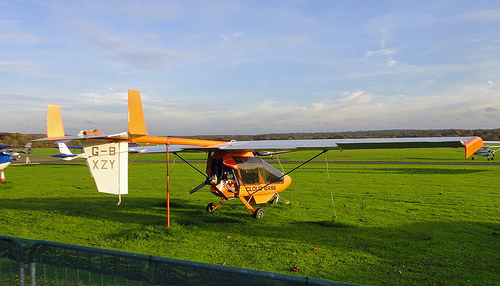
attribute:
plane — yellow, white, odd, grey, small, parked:
[19, 81, 485, 222]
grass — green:
[3, 145, 498, 283]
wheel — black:
[253, 209, 268, 224]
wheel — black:
[205, 202, 216, 215]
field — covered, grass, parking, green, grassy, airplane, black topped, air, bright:
[2, 120, 495, 283]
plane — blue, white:
[0, 147, 19, 183]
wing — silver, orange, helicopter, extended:
[129, 82, 490, 162]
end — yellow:
[125, 86, 145, 139]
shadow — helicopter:
[3, 184, 414, 257]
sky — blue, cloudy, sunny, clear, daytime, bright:
[2, 1, 499, 141]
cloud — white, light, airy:
[72, 75, 498, 128]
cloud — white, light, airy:
[340, 31, 500, 78]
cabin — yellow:
[198, 151, 294, 211]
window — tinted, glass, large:
[238, 153, 283, 187]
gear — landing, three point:
[200, 191, 293, 222]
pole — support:
[164, 144, 172, 230]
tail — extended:
[32, 86, 226, 152]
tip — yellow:
[125, 89, 148, 139]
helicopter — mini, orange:
[43, 89, 483, 227]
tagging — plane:
[78, 131, 131, 211]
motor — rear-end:
[184, 163, 232, 205]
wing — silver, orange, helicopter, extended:
[26, 103, 129, 148]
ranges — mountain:
[4, 126, 500, 149]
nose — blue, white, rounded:
[1, 154, 15, 169]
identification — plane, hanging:
[89, 130, 128, 198]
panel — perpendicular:
[210, 171, 223, 183]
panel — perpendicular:
[210, 156, 223, 164]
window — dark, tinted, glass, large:
[216, 169, 238, 189]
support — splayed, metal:
[237, 195, 255, 214]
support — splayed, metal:
[215, 199, 229, 212]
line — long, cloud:
[79, 84, 498, 137]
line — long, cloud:
[329, 40, 498, 85]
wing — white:
[86, 132, 130, 199]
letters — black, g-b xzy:
[90, 144, 115, 169]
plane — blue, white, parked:
[49, 138, 150, 164]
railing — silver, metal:
[3, 228, 403, 281]